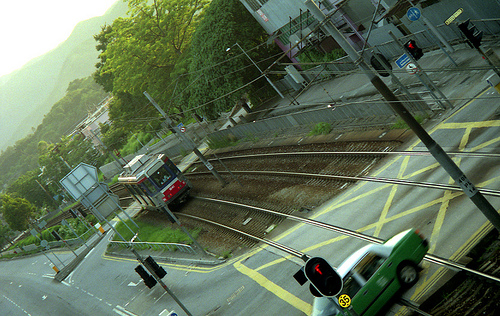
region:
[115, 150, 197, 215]
Red, white, and blue train car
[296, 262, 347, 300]
Stop sign signalling red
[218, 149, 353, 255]
Metal train tracks on the ground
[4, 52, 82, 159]
Green mountain range in the distance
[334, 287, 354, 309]
Yellow speed limit sign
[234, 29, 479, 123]
Fenced in parking lot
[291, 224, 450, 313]
Green and white taxi cab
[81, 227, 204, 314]
Metal sign post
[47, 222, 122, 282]
Concrete island with multiple signs on it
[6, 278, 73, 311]
White arrows painted on the street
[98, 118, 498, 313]
Yellow lines on the street.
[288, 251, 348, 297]
Walkway sign on the street.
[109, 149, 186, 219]
Train on the track.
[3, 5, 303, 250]
Trees in the background.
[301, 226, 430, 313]
Green car going over the tracks.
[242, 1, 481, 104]
Building in the background.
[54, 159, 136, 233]
Back of a sign.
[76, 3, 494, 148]
Buildings in the background.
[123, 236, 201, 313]
Street lights inthe street.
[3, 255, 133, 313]
White dotted lines in the street.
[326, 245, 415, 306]
Green car on yellow markings in road.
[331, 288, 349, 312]
35 in small yellow sign.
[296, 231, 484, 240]
Yellow lines marking the road.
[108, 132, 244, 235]
1 train car on tracks.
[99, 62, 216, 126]
Green leaves on trees.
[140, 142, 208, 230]
Train car is red, white, and gray.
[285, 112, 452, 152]
Metal fence near tracks.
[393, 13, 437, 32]
Blue and white sign attached to pole.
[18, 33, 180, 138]
Mountains in the background.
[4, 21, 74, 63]
Sky is bright beyond the mountains.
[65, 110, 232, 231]
the tram car on tracks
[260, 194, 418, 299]
a green car in the intersection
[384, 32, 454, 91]
this light is red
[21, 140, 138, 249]
the backs of signs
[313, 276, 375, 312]
the number is 35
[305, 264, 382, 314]
the sign is yellow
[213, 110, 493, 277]
two sets of train tracks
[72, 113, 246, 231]
the tram car is green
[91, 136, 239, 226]
this is public transportation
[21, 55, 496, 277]
this is a train crossing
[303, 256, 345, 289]
Red light is iilluminated.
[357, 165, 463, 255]
Yellow lines marking the road.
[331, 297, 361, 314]
Number 35 on sign.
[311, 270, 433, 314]
Green car driving over yellow lines.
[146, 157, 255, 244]
Train car driving on tracks.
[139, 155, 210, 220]
Train is red, white, and gray.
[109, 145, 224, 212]
Only one train car on tracks.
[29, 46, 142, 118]
Mountains in the distance.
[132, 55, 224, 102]
Green leaves on tree.